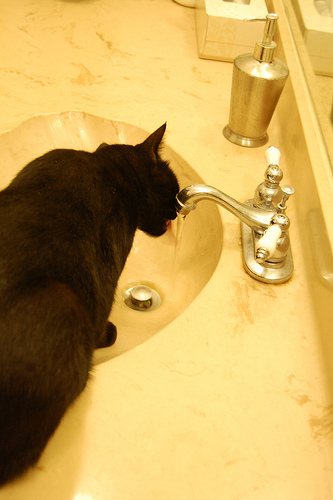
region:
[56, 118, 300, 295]
black cat drinking out of sink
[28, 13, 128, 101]
white marble bathroom counter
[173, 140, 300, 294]
brushed silver sink hardware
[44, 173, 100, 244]
thick black cat fur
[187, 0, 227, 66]
white cardboard tissue box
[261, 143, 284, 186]
brushed silver handle for faucet with white detail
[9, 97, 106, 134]
scalloped edge of bathroom sink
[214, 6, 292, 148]
brushed silver liquid soap dispenser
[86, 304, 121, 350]
black furry cat paw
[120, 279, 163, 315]
brushed silver sink plug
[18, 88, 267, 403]
a black cat inside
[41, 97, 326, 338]
a black cat that is inside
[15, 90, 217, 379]
a cat that is inside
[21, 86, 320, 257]
a cat drinking water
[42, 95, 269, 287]
a black cat drinking water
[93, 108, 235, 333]
a black cat drinking faucet water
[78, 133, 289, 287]
a drink cat drinking faucet water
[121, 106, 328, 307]
bathroom sink with water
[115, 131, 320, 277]
bathroom faucet with running water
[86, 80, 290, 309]
bathroom sink faucet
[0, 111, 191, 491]
a black is drinking water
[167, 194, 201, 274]
water running from faucet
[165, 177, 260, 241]
faucet is silver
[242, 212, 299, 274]
right handle of faucet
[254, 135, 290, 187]
left handle of faucet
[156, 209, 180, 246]
tongue of cat is pink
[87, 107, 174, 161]
pointy ears of cat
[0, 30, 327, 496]
counter of bathroom is yellow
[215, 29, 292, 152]
bottle of soap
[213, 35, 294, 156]
bottle is silver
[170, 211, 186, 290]
water coming from the faucet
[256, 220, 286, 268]
the white faucet handle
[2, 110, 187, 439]
A cat drinking water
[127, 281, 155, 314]
the plug in the sink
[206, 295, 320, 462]
the marble countertop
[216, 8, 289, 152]
the soap dispencer on the counter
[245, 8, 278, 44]
the nozzle of the dispenser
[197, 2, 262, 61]
kleenex on the counter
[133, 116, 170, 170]
the cats ear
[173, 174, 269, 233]
the faucet of the sink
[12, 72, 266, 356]
a black cat drinking from the faucet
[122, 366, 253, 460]
a marble counter top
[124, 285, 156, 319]
a silver sink stopper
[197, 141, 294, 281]
a silver sink faucet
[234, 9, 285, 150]
a silver soap dispenser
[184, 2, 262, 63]
a silver tissue box holder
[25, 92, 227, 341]
a oval sink with a drinking cat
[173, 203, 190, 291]
running water under the faucet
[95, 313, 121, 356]
a black cat paw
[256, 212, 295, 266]
silver and marble faucet